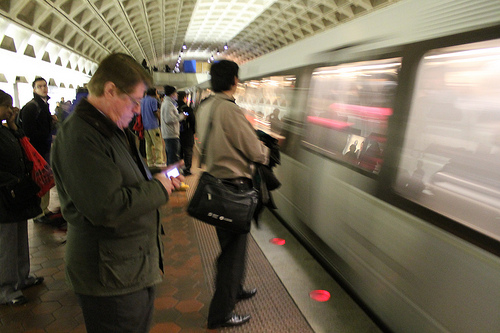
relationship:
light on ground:
[307, 289, 333, 303] [0, 138, 386, 329]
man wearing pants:
[140, 87, 167, 172] [142, 127, 168, 166]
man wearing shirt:
[140, 87, 167, 172] [140, 95, 159, 128]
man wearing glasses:
[51, 53, 185, 333] [116, 85, 146, 108]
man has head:
[140, 87, 167, 172] [145, 85, 157, 98]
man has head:
[51, 53, 185, 333] [89, 55, 147, 131]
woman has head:
[0, 89, 45, 305] [0, 90, 14, 121]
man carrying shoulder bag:
[194, 60, 268, 328] [186, 100, 257, 235]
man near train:
[194, 60, 268, 328] [176, 1, 498, 329]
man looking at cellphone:
[51, 53, 185, 333] [159, 163, 186, 180]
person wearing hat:
[160, 84, 188, 166] [163, 83, 177, 98]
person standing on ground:
[160, 84, 188, 166] [0, 138, 386, 329]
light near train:
[307, 289, 333, 303] [176, 1, 498, 329]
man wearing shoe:
[194, 60, 268, 328] [210, 312, 254, 327]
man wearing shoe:
[194, 60, 268, 328] [236, 287, 259, 301]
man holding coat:
[194, 60, 268, 328] [254, 125, 285, 232]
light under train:
[307, 289, 333, 303] [176, 1, 498, 329]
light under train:
[268, 234, 287, 246] [176, 1, 498, 329]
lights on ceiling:
[206, 45, 230, 65] [1, 0, 395, 71]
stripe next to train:
[249, 206, 381, 333] [176, 1, 498, 329]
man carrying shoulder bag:
[140, 87, 167, 172] [186, 100, 257, 235]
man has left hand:
[51, 53, 185, 333] [164, 158, 192, 190]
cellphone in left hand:
[159, 163, 186, 180] [164, 158, 192, 190]